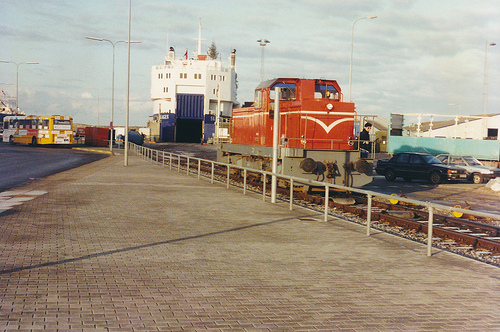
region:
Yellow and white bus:
[3, 113, 75, 145]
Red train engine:
[228, 78, 365, 172]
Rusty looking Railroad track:
[356, 191, 498, 252]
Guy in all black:
[358, 120, 373, 167]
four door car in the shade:
[376, 151, 464, 186]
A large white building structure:
[153, 55, 230, 144]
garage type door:
[174, 93, 202, 141]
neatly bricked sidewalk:
[58, 171, 250, 329]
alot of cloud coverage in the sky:
[379, 6, 477, 112]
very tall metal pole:
[125, 1, 133, 167]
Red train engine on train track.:
[213, 78, 379, 200]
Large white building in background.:
[144, 15, 235, 153]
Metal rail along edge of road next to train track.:
[291, 168, 499, 299]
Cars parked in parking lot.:
[373, 145, 495, 185]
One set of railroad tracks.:
[356, 191, 496, 263]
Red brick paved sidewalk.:
[125, 208, 327, 318]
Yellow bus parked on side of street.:
[2, 110, 75, 151]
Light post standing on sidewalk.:
[83, 26, 145, 168]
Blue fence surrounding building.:
[386, 128, 498, 160]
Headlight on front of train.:
[318, 100, 343, 117]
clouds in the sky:
[385, 0, 480, 95]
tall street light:
[341, 1, 381, 86]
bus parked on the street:
[0, 100, 85, 152]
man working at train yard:
[340, 102, 385, 214]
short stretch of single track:
[365, 185, 495, 261]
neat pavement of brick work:
[20, 215, 240, 327]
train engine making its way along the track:
[205, 62, 382, 217]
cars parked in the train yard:
[375, 135, 496, 192]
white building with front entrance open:
[141, 22, 241, 157]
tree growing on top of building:
[200, 30, 225, 67]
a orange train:
[211, 73, 373, 151]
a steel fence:
[251, 180, 399, 242]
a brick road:
[110, 186, 263, 291]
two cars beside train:
[363, 148, 499, 183]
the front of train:
[301, 81, 360, 153]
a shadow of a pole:
[1, 190, 326, 279]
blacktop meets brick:
[0, 145, 107, 185]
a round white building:
[127, 28, 237, 141]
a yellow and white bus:
[3, 107, 73, 151]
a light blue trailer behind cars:
[379, 105, 498, 162]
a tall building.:
[131, 11, 259, 142]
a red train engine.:
[221, 64, 367, 198]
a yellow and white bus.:
[0, 102, 85, 152]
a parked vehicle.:
[67, 107, 125, 151]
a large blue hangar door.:
[169, 86, 206, 156]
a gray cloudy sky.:
[1, 1, 495, 127]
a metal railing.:
[119, 140, 499, 275]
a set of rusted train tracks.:
[130, 140, 497, 254]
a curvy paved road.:
[0, 142, 111, 187]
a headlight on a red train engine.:
[294, 136, 314, 148]